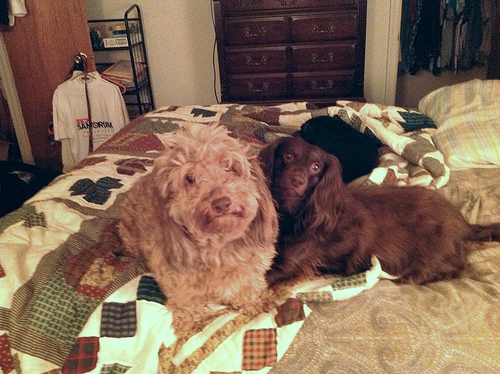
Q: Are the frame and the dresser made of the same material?
A: Yes, both the frame and the dresser are made of wood.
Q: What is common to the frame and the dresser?
A: The material, both the frame and the dresser are wooden.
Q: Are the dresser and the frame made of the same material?
A: Yes, both the dresser and the frame are made of wood.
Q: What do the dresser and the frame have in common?
A: The material, both the dresser and the frame are wooden.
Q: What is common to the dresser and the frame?
A: The material, both the dresser and the frame are wooden.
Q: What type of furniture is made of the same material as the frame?
A: The dresser is made of the same material as the frame.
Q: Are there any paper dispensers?
A: No, there are no paper dispensers.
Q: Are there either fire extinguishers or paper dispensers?
A: No, there are no paper dispensers or fire extinguishers.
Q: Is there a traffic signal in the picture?
A: No, there are no traffic lights.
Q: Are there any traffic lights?
A: No, there are no traffic lights.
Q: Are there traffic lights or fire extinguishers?
A: No, there are no traffic lights or fire extinguishers.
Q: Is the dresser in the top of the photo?
A: Yes, the dresser is in the top of the image.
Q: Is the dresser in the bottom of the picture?
A: No, the dresser is in the top of the image.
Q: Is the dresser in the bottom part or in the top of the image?
A: The dresser is in the top of the image.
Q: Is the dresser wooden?
A: Yes, the dresser is wooden.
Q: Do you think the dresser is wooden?
A: Yes, the dresser is wooden.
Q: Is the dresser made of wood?
A: Yes, the dresser is made of wood.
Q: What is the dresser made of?
A: The dresser is made of wood.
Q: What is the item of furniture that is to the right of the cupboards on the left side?
A: The piece of furniture is a dresser.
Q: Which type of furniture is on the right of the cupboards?
A: The piece of furniture is a dresser.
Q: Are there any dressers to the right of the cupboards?
A: Yes, there is a dresser to the right of the cupboards.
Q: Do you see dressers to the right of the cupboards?
A: Yes, there is a dresser to the right of the cupboards.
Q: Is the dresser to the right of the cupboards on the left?
A: Yes, the dresser is to the right of the cupboards.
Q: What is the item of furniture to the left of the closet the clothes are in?
A: The piece of furniture is a dresser.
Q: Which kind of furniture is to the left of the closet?
A: The piece of furniture is a dresser.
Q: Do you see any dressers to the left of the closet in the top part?
A: Yes, there is a dresser to the left of the closet.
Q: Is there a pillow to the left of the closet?
A: No, there is a dresser to the left of the closet.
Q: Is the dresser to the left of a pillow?
A: No, the dresser is to the left of the closet.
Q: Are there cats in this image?
A: No, there are no cats.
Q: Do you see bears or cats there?
A: No, there are no cats or bears.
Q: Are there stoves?
A: No, there are no stoves.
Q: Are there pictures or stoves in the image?
A: No, there are no stoves or pictures.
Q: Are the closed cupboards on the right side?
A: No, the cupboards are on the left of the image.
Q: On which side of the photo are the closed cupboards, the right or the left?
A: The cupboards are on the left of the image.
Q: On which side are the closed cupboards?
A: The cupboards are on the left of the image.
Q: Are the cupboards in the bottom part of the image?
A: No, the cupboards are in the top of the image.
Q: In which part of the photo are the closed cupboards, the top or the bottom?
A: The cupboards are in the top of the image.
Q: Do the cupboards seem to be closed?
A: Yes, the cupboards are closed.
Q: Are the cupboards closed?
A: Yes, the cupboards are closed.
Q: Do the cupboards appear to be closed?
A: Yes, the cupboards are closed.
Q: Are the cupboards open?
A: No, the cupboards are closed.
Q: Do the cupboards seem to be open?
A: No, the cupboards are closed.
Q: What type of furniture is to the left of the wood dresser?
A: The pieces of furniture are cupboards.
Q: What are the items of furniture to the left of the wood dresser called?
A: The pieces of furniture are cupboards.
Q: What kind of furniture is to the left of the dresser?
A: The pieces of furniture are cupboards.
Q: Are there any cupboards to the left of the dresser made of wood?
A: Yes, there are cupboards to the left of the dresser.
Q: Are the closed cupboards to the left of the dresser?
A: Yes, the cupboards are to the left of the dresser.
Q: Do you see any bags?
A: No, there are no bags.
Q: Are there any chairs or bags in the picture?
A: No, there are no bags or chairs.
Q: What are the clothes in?
A: The clothes are in the closet.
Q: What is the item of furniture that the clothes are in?
A: The piece of furniture is a closet.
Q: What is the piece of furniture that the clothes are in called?
A: The piece of furniture is a closet.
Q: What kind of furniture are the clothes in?
A: The clothes are in the closet.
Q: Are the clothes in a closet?
A: Yes, the clothes are in a closet.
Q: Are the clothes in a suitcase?
A: No, the clothes are in a closet.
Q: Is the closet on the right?
A: Yes, the closet is on the right of the image.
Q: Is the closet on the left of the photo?
A: No, the closet is on the right of the image.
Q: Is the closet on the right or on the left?
A: The closet is on the right of the image.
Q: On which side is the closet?
A: The closet is on the right of the image.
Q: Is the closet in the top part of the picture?
A: Yes, the closet is in the top of the image.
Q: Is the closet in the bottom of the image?
A: No, the closet is in the top of the image.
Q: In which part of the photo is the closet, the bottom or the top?
A: The closet is in the top of the image.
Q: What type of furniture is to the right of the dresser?
A: The piece of furniture is a closet.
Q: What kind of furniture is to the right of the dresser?
A: The piece of furniture is a closet.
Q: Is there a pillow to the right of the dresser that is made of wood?
A: No, there is a closet to the right of the dresser.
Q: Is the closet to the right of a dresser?
A: Yes, the closet is to the right of a dresser.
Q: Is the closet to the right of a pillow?
A: No, the closet is to the right of a dresser.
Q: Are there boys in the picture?
A: No, there are no boys.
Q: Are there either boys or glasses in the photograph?
A: No, there are no boys or glasses.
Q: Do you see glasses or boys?
A: No, there are no boys or glasses.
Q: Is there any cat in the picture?
A: No, there are no cats.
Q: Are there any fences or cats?
A: No, there are no cats or fences.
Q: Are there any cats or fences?
A: No, there are no cats or fences.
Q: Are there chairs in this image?
A: No, there are no chairs.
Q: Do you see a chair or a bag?
A: No, there are no chairs or bags.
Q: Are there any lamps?
A: No, there are no lamps.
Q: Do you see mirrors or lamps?
A: No, there are no lamps or mirrors.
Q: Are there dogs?
A: Yes, there is a dog.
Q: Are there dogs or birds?
A: Yes, there is a dog.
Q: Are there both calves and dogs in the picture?
A: No, there is a dog but no calves.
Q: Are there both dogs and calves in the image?
A: No, there is a dog but no calves.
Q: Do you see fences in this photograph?
A: No, there are no fences.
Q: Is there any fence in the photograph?
A: No, there are no fences.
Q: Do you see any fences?
A: No, there are no fences.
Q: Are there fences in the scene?
A: No, there are no fences.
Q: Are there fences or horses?
A: No, there are no fences or horses.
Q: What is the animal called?
A: The animal is a dog.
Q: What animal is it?
A: The animal is a dog.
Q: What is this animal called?
A: That is a dog.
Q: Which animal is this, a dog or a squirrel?
A: That is a dog.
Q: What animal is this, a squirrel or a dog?
A: That is a dog.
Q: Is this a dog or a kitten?
A: This is a dog.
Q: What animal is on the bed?
A: The dog is on the bed.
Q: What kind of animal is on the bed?
A: The animal is a dog.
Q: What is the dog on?
A: The dog is on the bed.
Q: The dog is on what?
A: The dog is on the bed.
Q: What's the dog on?
A: The dog is on the bed.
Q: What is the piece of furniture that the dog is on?
A: The piece of furniture is a bed.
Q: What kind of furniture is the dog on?
A: The dog is on the bed.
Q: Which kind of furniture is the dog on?
A: The dog is on the bed.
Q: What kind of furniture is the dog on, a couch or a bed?
A: The dog is on a bed.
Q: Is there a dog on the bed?
A: Yes, there is a dog on the bed.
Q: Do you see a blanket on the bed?
A: No, there is a dog on the bed.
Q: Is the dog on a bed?
A: Yes, the dog is on a bed.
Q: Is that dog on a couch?
A: No, the dog is on a bed.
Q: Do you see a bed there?
A: Yes, there is a bed.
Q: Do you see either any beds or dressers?
A: Yes, there is a bed.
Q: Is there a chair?
A: No, there are no chairs.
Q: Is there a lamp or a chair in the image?
A: No, there are no chairs or lamps.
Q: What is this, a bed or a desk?
A: This is a bed.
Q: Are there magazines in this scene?
A: No, there are no magazines.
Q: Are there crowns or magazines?
A: No, there are no magazines or crowns.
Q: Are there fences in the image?
A: No, there are no fences.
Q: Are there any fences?
A: No, there are no fences.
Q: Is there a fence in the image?
A: No, there are no fences.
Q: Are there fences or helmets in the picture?
A: No, there are no fences or helmets.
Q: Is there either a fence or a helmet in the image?
A: No, there are no fences or helmets.